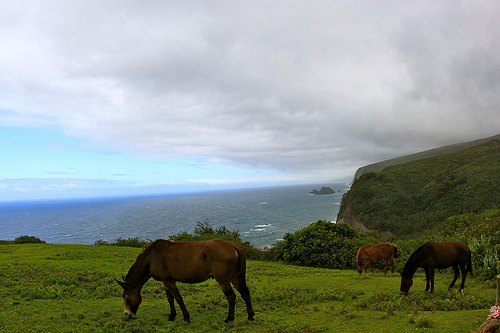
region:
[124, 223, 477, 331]
three horses grazing on grass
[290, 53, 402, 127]
gray clouds in sky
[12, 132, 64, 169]
blue of daytime sky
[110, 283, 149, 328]
head of grazing horse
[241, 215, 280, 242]
white caps of choppy water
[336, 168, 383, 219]
edge of green cliff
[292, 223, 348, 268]
leaves of green bush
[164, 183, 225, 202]
sky and ocean on horizon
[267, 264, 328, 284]
green grass on hill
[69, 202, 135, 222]
surface of blue water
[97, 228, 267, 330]
Horse grazing in a field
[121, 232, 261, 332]
Horse grazing on a mountaintop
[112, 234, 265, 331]
Horse eating grass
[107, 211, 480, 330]
Horses grazing in a field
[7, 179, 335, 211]
Horizon as seen from a mountaintop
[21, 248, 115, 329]
Grassy field on a mountain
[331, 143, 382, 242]
Steep cliff on a mountainside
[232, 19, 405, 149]
Sky of an overcast day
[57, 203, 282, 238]
Large body of water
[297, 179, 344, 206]
Large boulder jutting out of the water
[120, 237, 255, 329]
brown horse eating grass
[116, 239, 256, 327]
horse standing in field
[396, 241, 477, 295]
horse eating in field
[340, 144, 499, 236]
cliff next to ocean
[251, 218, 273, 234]
white cap in ocean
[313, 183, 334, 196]
rock formed in ocean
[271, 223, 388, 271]
green bush on field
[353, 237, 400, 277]
wild horse eating grass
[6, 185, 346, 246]
ocean next to mountain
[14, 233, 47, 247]
green bush in grass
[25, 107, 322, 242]
majestic view in the distance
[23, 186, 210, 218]
blue haze on the horizon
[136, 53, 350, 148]
stormy gray skies gathering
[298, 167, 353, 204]
small land cluster in the horizon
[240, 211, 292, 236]
white house in the distance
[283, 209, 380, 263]
lush green vegetation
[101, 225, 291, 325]
brown horse grazing on the ground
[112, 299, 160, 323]
white mouth on the horse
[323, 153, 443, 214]
small hill covered with green trees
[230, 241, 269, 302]
black tail on horse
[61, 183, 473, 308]
Three horses in the field.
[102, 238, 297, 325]
The horse is eating grass.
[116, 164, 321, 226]
The city is in the background.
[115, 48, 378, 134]
The sky is dark and cloudy.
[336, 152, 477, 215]
grass on top of the hill.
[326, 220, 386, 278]
The little horse is standing alone.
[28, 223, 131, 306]
The grass is green.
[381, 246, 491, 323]
The horse is brown.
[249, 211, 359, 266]
The bushes is behind the horse.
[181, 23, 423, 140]
The sky has clouds.